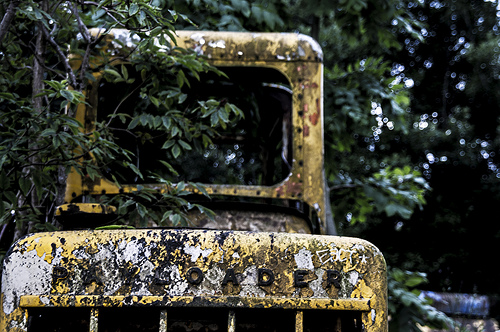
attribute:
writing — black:
[20, 230, 347, 309]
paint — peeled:
[7, 232, 68, 292]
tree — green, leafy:
[122, 81, 248, 181]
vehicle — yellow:
[31, 16, 388, 319]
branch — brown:
[13, 28, 64, 163]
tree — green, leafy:
[113, 74, 199, 157]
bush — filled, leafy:
[358, 120, 466, 279]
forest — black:
[4, 0, 497, 328]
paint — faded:
[0, 227, 379, 305]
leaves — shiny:
[357, 79, 419, 223]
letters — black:
[49, 262, 345, 288]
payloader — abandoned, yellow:
[0, 26, 498, 330]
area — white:
[1, 247, 63, 312]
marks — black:
[155, 228, 185, 250]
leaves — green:
[121, 36, 249, 172]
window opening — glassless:
[80, 60, 298, 186]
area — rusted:
[275, 170, 309, 197]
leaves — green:
[49, 28, 219, 227]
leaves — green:
[125, 75, 200, 162]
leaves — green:
[148, 89, 232, 174]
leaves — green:
[133, 92, 232, 161]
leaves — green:
[130, 82, 234, 163]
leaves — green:
[143, 118, 193, 169]